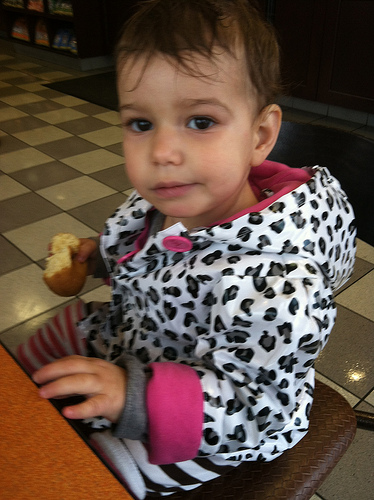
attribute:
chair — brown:
[140, 379, 356, 499]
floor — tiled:
[44, 161, 138, 213]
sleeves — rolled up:
[117, 357, 325, 453]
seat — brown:
[52, 314, 347, 497]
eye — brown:
[124, 118, 154, 134]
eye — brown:
[184, 111, 220, 132]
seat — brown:
[293, 434, 340, 476]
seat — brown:
[189, 377, 372, 497]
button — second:
[116, 243, 142, 264]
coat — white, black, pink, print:
[72, 157, 359, 464]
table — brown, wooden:
[1, 346, 135, 498]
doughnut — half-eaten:
[37, 228, 91, 297]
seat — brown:
[238, 359, 347, 476]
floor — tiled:
[27, 110, 138, 209]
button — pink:
[162, 235, 189, 253]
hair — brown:
[109, 3, 287, 102]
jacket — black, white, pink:
[60, 158, 362, 497]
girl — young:
[30, 8, 358, 497]